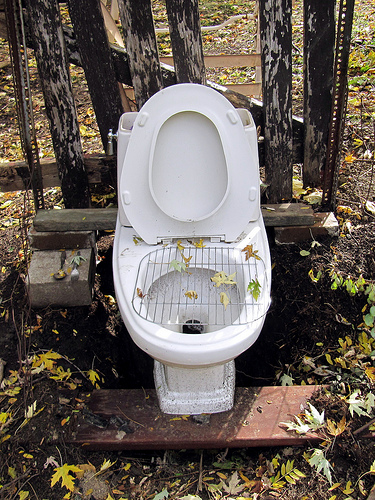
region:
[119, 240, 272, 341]
grill grate over the toilet bowl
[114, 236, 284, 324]
fall leaves on top of the grate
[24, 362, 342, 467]
toilet is sitting on top of a piece of wood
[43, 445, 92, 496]
bright yellow autumn leaf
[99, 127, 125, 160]
shiny silver toliet handle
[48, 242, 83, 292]
set of silverware over by the toilet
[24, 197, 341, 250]
2 by 4 behind the toliet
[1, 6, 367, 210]
two rusted metal rod going into the ground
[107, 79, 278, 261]
the toliet seat is flipped up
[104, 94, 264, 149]
top piece of the toilet is missing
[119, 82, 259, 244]
A white toilet seat that's up.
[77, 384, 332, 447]
A red board under a white toilet front.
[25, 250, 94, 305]
A long grey cinder block.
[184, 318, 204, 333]
A black hole in a toilet.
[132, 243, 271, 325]
A silver grate over a toilet.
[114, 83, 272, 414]
A white toilet in the woods.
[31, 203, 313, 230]
A grey long board behind the toilet.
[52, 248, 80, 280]
A spoon and a fork on a cinder block.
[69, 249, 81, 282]
A silver fork with a leaf on it.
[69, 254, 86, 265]
Green leaf on a silver fork.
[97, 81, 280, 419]
white toilet in forest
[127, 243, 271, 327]
metal grill on top of toilet seat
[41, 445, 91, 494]
yellow leaf on the ground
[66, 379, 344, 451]
wood panel underneath toilet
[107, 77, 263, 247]
raised toilet lid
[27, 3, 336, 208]
brown and white tree trunks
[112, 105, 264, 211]
open toilet tank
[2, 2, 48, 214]
metal rail with holes in it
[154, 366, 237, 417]
brown dirt on base of toilet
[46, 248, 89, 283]
fork and spoon on cement block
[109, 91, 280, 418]
white toilet in the woods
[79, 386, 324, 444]
wood plank supporting base of toilet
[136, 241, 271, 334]
grate covering toilet bowl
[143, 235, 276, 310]
leaves on top of the grate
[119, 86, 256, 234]
raised seat of the toilet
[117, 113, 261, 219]
tank of the white toilet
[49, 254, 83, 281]
spoon and fork sitting on cinder block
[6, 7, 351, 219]
tree trunks behind the toilet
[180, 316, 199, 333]
drain hole in the toilet bowl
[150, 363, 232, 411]
base of the toilet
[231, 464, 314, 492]
Autumn leaves nearby toilet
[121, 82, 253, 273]
Raised white toilet lid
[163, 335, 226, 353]
Part of white toilet bowl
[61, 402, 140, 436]
Part of wooden support board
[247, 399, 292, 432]
Part of wooden support bowl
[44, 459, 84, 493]
Beautiful golden autumn leaf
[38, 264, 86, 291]
Part of concrete slab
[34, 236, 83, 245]
Part of red brick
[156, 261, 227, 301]
Part of metal rack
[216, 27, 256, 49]
Part of ground behind toilet